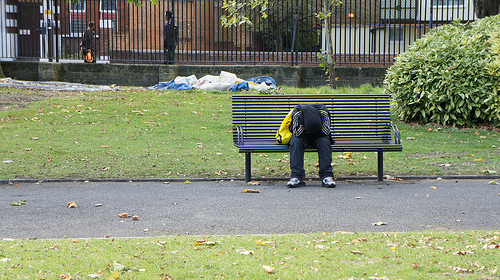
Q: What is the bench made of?
A: Metal.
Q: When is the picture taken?
A: Daytime.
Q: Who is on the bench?
A: A man.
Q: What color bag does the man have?
A: Yellow.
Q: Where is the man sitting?
A: On a bench.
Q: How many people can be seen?
A: 3.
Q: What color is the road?
A: Gray.